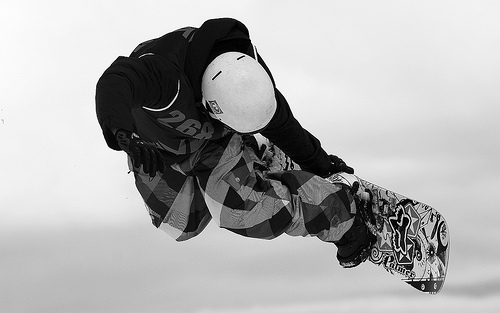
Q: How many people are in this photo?
A: One.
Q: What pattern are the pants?
A: Checkered.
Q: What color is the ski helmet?
A: White.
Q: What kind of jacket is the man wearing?
A: A ski jacket.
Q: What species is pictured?
A: Homo Sapien.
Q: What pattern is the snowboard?
A: Busy.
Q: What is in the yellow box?
A: The snowboarder's left arm.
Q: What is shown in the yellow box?
A: The left leg of the snowboarder.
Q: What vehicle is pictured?
A: Snowboard.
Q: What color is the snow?
A: White.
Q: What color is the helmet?
A: White.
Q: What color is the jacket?
A: Black.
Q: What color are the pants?
A: Gray.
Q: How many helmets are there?
A: One.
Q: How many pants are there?
A: One.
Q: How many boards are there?
A: One.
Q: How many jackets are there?
A: One.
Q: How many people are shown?
A: 1.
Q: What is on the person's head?
A: Helmet.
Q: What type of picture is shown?
A: Black and white.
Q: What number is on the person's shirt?
A: 268.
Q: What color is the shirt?
A: Black.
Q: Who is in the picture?
A: A snowboarder.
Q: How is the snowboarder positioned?
A: He is leaning left.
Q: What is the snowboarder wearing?
A: A helmet.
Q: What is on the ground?
A: Snow.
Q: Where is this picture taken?
A: On the ski slope.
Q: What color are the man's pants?
A: Black and white.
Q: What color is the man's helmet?
A: White.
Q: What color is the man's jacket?
A: Black.